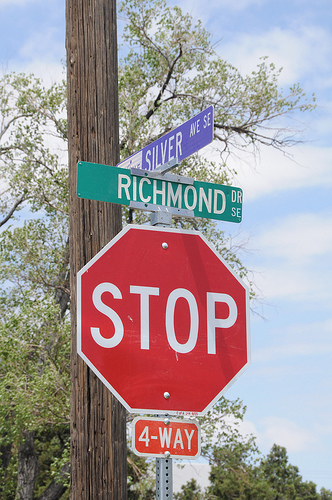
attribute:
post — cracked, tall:
[151, 465, 188, 499]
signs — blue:
[91, 119, 270, 478]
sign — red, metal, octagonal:
[131, 420, 200, 456]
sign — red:
[51, 227, 267, 404]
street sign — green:
[71, 155, 245, 221]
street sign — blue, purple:
[120, 101, 226, 179]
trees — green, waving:
[7, 241, 69, 443]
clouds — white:
[272, 157, 331, 206]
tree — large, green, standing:
[130, 35, 226, 105]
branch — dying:
[223, 115, 272, 145]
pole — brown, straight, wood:
[70, 43, 114, 134]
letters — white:
[132, 271, 158, 356]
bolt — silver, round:
[154, 232, 175, 259]